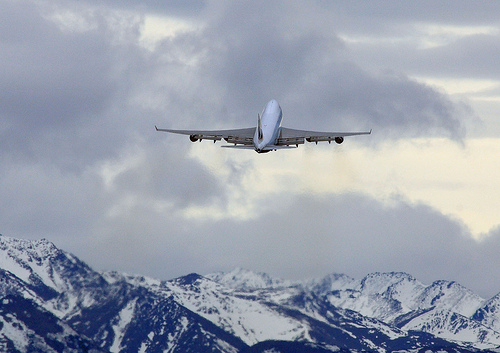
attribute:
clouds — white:
[2, 5, 482, 147]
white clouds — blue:
[342, 23, 486, 158]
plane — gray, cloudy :
[150, 98, 371, 156]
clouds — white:
[365, 43, 462, 168]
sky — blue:
[31, 29, 213, 141]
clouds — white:
[2, 2, 498, 282]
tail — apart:
[254, 113, 267, 146]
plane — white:
[152, 84, 374, 160]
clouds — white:
[163, 196, 234, 300]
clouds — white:
[97, 181, 478, 278]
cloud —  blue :
[162, 3, 469, 145]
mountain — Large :
[190, 259, 493, 345]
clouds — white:
[1, 3, 148, 158]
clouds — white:
[0, 157, 117, 238]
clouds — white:
[81, 190, 485, 299]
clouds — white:
[106, 147, 233, 217]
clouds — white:
[154, 18, 484, 158]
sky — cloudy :
[2, 0, 485, 300]